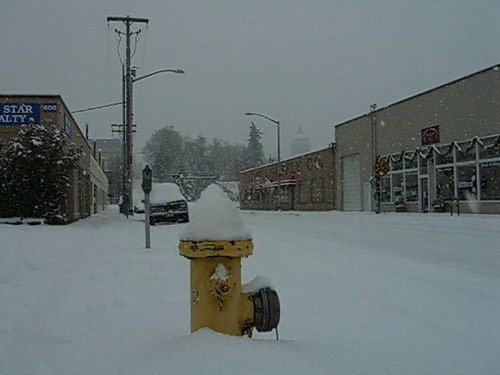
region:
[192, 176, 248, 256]
snow on top of fire hydrant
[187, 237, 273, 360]
fire plug is yellow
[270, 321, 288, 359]
chain hanging from fire plug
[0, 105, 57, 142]
sign on building is blue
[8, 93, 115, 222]
building is brown brick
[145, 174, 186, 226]
truck is snow covered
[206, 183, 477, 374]
deep snow in middle of street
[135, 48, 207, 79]
sodium lamp over snow covered truck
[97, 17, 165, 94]
sodium lamp on telephone pole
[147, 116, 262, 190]
pine trees in background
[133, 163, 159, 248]
parking meter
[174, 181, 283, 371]
yellow fire hydrant surrounded and covered with snow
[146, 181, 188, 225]
large vehicle covered with snow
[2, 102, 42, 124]
blue and white sign on a building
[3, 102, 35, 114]
blue sign with white text reading STAR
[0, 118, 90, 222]
trees covered in snow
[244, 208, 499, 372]
snow covering the street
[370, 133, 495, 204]
windows on a store building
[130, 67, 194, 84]
street light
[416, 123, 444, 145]
store sign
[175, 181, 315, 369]
snow coered fire hydrant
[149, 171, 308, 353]
yellow fire hydrant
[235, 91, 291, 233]
city street light on metal pole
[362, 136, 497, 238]
green garland on outside of building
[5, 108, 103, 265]
tree with snow on limbs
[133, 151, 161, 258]
parking meter on metal pole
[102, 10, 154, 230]
wooden pole with power lines attached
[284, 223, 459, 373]
snow covered street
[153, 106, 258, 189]
snow covered trees in the distance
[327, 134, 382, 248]
white door on building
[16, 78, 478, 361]
street covered in snow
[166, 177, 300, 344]
yellow fire hydrant on curb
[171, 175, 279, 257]
snow piled up on hydrant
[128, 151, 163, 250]
parking meter on curb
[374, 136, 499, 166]
christmas garland on building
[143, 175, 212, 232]
car covered in snow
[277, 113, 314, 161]
building shrouded in fog in distance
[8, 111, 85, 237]
bush being covered in snow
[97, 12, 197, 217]
tall electrical pole on curb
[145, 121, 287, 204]
trees in the distance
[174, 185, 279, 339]
a snow covered yellow fire hydrant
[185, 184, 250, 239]
a pile of snow on the hydrant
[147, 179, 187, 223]
a car parked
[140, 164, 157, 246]
a parking meter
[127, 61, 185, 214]
a tall street light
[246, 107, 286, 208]
a tall street light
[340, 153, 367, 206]
a white garage door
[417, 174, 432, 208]
a glass door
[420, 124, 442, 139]
a sign on the building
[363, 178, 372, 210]
a white doorway